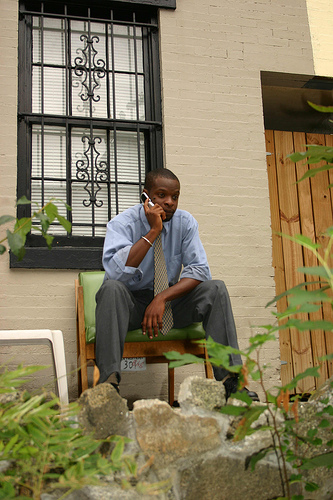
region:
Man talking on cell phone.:
[44, 92, 266, 408]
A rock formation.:
[46, 373, 322, 499]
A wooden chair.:
[67, 263, 216, 394]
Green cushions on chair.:
[74, 264, 216, 357]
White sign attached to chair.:
[113, 352, 152, 375]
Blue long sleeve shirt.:
[103, 195, 221, 298]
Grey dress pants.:
[86, 266, 252, 392]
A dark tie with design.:
[144, 227, 176, 333]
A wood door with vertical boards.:
[264, 121, 331, 400]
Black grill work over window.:
[19, 8, 156, 260]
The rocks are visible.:
[73, 376, 163, 477]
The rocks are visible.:
[106, 388, 238, 492]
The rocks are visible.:
[66, 297, 224, 493]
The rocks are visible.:
[111, 397, 177, 461]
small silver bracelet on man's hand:
[132, 229, 163, 252]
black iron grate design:
[46, 29, 124, 117]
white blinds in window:
[26, 51, 163, 117]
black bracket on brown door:
[283, 389, 323, 416]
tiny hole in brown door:
[315, 192, 331, 208]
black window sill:
[5, 235, 91, 275]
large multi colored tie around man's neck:
[144, 248, 179, 323]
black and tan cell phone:
[134, 188, 157, 223]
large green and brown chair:
[58, 271, 157, 358]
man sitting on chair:
[63, 169, 241, 335]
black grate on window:
[22, 0, 157, 237]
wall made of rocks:
[51, 372, 328, 491]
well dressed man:
[88, 166, 257, 396]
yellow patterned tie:
[149, 227, 170, 331]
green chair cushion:
[83, 266, 206, 340]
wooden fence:
[266, 130, 332, 394]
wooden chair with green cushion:
[68, 268, 215, 401]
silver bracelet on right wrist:
[132, 228, 155, 251]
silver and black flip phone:
[135, 188, 160, 220]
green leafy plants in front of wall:
[0, 359, 133, 498]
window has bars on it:
[27, 13, 153, 234]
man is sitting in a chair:
[105, 177, 243, 393]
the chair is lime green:
[74, 279, 212, 356]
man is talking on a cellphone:
[128, 185, 179, 233]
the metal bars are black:
[26, 8, 159, 220]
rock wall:
[73, 394, 328, 498]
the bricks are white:
[185, 40, 248, 188]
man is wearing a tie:
[143, 220, 191, 327]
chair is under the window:
[67, 219, 115, 383]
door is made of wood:
[271, 140, 331, 355]